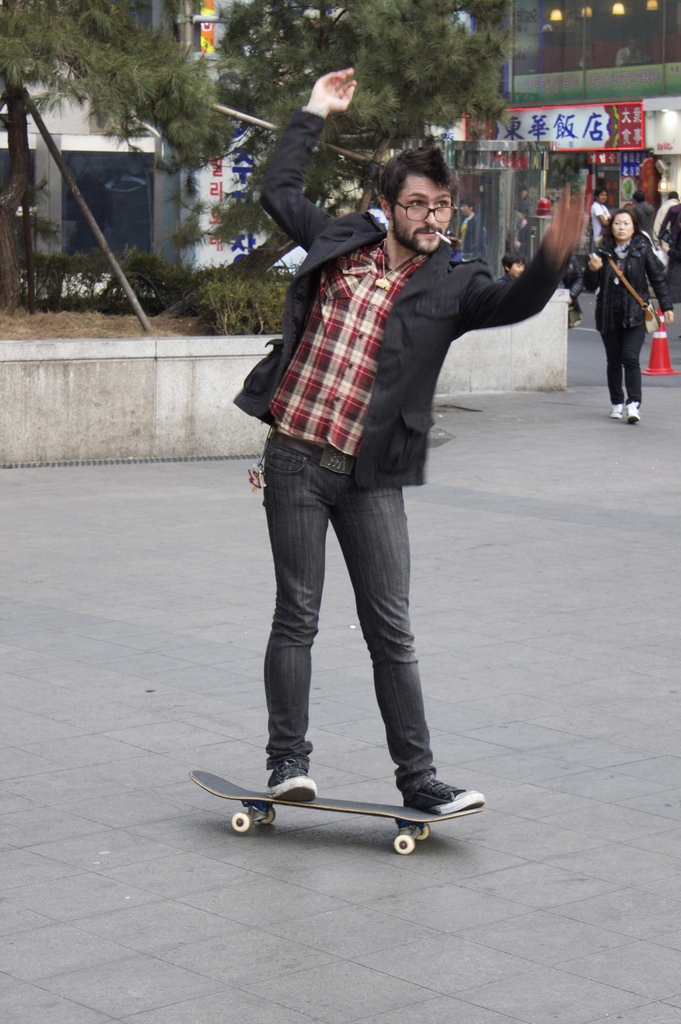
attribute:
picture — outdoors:
[4, 1, 677, 1021]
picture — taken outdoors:
[14, 42, 652, 918]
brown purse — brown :
[599, 240, 662, 337]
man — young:
[229, 64, 594, 815]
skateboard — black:
[186, 767, 484, 854]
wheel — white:
[231, 811, 252, 833]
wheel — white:
[260, 806, 274, 825]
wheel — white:
[392, 832, 415, 855]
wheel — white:
[414, 820, 431, 841]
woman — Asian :
[594, 193, 659, 394]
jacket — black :
[588, 229, 658, 321]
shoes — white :
[593, 403, 647, 437]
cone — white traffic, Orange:
[653, 305, 660, 354]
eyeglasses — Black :
[389, 191, 454, 221]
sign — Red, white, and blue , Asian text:
[515, 102, 645, 152]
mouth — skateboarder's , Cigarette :
[411, 225, 458, 243]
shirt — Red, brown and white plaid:
[281, 250, 392, 469]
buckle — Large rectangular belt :
[301, 444, 361, 457]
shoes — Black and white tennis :
[261, 742, 504, 828]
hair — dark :
[402, 139, 456, 178]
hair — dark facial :
[389, 210, 436, 263]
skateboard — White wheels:
[199, 754, 504, 861]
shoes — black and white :
[264, 756, 505, 829]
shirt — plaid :
[280, 225, 414, 476]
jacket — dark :
[256, 116, 572, 506]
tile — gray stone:
[482, 895, 583, 938]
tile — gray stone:
[363, 978, 655, 1016]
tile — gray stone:
[494, 932, 631, 998]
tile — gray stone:
[499, 955, 658, 988]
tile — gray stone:
[493, 896, 650, 975]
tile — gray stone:
[500, 906, 637, 984]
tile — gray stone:
[549, 933, 660, 988]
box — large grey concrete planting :
[14, 305, 589, 435]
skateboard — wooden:
[180, 765, 489, 860]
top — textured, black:
[181, 770, 479, 818]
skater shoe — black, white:
[400, 771, 489, 816]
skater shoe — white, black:
[263, 768, 319, 805]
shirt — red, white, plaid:
[263, 243, 438, 457]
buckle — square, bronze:
[315, 445, 353, 477]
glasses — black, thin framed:
[390, 198, 456, 227]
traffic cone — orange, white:
[626, 300, 660, 379]